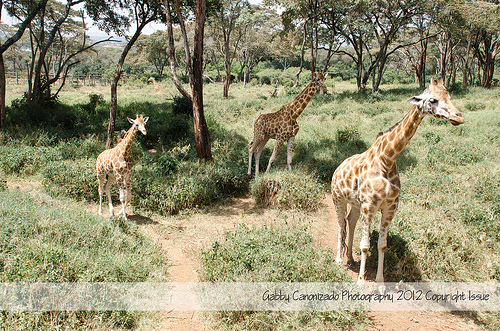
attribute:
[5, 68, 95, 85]
gate — distance , wooden 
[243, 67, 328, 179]
giraffe — spotted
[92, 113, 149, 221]
giraffe — spotted 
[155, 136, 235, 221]
bushes — long patch 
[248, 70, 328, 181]
adult giraffe —  adult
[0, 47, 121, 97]
fence —  behind 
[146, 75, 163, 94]
giraffe — distance 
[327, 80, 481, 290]
giraffe — baby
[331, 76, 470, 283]
giraffes — spotted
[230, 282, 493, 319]
name — photography company 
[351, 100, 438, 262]
giraffe — standing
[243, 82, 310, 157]
giraffe — standing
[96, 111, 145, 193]
giraffe — standing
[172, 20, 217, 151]
tree — grove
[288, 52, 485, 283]
giraffe — young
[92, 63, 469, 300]
giraffe's walking — Three 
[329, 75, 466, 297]
giraffe — spotted , leaning forward, three , standing,  together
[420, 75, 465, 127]
head — leaning forward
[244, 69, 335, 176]
giraffe — spotted 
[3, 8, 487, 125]
trees — spots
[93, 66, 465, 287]
giraffes. —  behind 